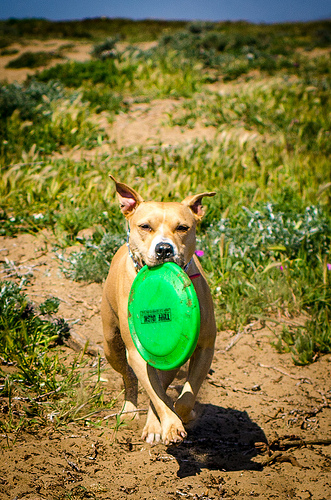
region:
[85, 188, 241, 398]
the dog is holding a frisbee in his mouth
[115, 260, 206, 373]
the frisbee is green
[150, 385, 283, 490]
shadow of the dog on the dirt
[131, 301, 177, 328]
black writing on the frisbee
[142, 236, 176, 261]
the nose is black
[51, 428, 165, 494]
the dirt is brown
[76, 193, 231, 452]
the dog is tan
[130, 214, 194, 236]
the eyes are open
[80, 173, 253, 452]
the dog is in motion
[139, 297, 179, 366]
the frisbee is green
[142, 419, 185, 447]
paws of the dog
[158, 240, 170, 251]
nose of the dog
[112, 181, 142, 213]
ear of the dog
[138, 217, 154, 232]
eye of the dog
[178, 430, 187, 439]
claws of the dog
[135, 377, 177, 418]
leg of the dog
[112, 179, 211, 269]
the head of a dog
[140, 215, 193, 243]
the eyes of a dog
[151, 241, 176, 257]
the black nose of a dog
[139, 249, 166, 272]
the lips of a dog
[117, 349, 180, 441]
the right leg of a dog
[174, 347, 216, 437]
the left leg of a dog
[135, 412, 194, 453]
the paws of a dog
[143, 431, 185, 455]
the sharp claws of a dog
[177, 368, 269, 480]
the shadow of a dog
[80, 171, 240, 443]
pitbull holding a frisbee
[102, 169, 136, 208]
right ear of dog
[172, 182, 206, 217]
left ear of dog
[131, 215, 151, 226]
right eye of dog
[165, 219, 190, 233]
left eye of dog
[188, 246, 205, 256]
pink colored top of flower